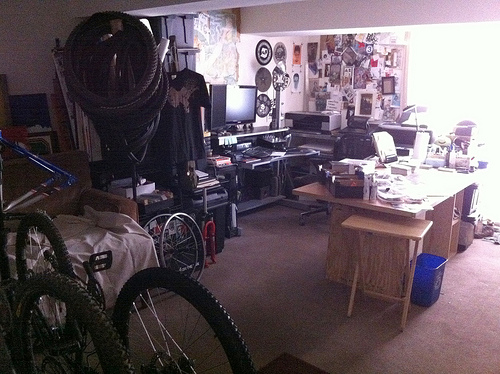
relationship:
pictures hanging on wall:
[254, 35, 295, 129] [242, 0, 498, 176]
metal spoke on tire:
[131, 297, 167, 365] [112, 266, 252, 371]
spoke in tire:
[129, 285, 191, 372] [107, 272, 244, 363]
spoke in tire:
[129, 285, 191, 372] [97, 255, 257, 372]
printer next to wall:
[276, 106, 345, 132] [258, 36, 362, 158]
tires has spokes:
[2, 193, 265, 369] [53, 300, 195, 365]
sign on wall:
[257, 90, 274, 121] [235, 24, 300, 121]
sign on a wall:
[307, 42, 317, 59] [291, 64, 322, 122]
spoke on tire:
[129, 285, 191, 372] [106, 255, 281, 369]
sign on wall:
[269, 40, 289, 72] [238, 2, 499, 239]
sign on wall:
[273, 70, 297, 95] [239, 36, 307, 131]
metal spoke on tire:
[131, 297, 167, 365] [106, 260, 256, 372]